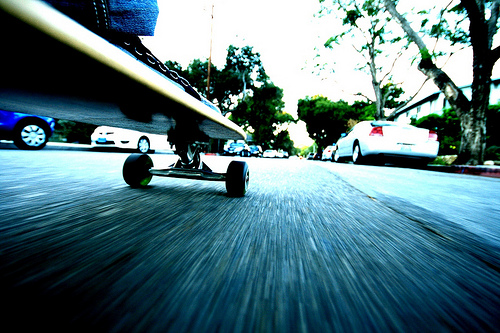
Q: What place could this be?
A: It is a street.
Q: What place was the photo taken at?
A: It was taken at the street.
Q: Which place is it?
A: It is a street.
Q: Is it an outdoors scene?
A: Yes, it is outdoors.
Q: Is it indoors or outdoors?
A: It is outdoors.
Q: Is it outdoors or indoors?
A: It is outdoors.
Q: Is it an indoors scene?
A: No, it is outdoors.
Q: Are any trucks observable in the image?
A: Yes, there is a truck.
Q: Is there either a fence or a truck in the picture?
A: Yes, there is a truck.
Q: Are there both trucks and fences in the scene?
A: No, there is a truck but no fences.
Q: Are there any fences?
A: No, there are no fences.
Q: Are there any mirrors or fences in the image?
A: No, there are no fences or mirrors.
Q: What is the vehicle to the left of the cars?
A: The vehicle is a truck.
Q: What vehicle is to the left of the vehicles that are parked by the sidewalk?
A: The vehicle is a truck.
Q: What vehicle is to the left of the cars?
A: The vehicle is a truck.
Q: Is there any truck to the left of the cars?
A: Yes, there is a truck to the left of the cars.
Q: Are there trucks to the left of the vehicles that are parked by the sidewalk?
A: Yes, there is a truck to the left of the cars.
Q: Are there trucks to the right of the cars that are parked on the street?
A: No, the truck is to the left of the cars.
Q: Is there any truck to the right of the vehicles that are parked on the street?
A: No, the truck is to the left of the cars.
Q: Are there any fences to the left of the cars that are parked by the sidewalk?
A: No, there is a truck to the left of the cars.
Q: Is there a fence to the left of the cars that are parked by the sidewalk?
A: No, there is a truck to the left of the cars.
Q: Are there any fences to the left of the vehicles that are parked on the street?
A: No, there is a truck to the left of the cars.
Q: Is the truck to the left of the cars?
A: Yes, the truck is to the left of the cars.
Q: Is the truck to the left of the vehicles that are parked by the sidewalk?
A: Yes, the truck is to the left of the cars.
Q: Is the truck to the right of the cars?
A: No, the truck is to the left of the cars.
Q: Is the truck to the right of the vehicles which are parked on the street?
A: No, the truck is to the left of the cars.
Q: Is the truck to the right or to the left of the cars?
A: The truck is to the left of the cars.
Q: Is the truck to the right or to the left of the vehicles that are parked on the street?
A: The truck is to the left of the cars.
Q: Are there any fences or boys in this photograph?
A: No, there are no boys or fences.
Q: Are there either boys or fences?
A: No, there are no boys or fences.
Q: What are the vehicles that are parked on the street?
A: The vehicles are cars.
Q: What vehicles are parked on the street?
A: The vehicles are cars.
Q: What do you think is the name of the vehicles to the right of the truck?
A: The vehicles are cars.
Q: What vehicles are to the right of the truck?
A: The vehicles are cars.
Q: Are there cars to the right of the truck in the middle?
A: Yes, there are cars to the right of the truck.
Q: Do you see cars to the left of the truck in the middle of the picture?
A: No, the cars are to the right of the truck.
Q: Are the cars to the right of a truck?
A: Yes, the cars are to the right of a truck.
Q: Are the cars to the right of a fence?
A: No, the cars are to the right of a truck.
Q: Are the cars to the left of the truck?
A: No, the cars are to the right of the truck.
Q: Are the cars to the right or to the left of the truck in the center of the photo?
A: The cars are to the right of the truck.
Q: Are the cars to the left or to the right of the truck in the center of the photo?
A: The cars are to the right of the truck.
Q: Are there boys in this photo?
A: No, there are no boys.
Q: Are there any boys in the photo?
A: No, there are no boys.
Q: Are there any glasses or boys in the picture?
A: No, there are no boys or glasses.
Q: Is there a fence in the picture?
A: No, there are no fences.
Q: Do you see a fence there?
A: No, there are no fences.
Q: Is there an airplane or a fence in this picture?
A: No, there are no fences or airplanes.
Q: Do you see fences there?
A: No, there are no fences.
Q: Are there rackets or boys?
A: No, there are no boys or rackets.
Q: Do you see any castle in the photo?
A: No, there are no castles.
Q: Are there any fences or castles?
A: No, there are no castles or fences.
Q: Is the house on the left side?
A: No, the house is on the right of the image.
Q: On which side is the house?
A: The house is on the right of the image.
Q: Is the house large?
A: Yes, the house is large.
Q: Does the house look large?
A: Yes, the house is large.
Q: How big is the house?
A: The house is large.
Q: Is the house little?
A: No, the house is large.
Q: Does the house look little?
A: No, the house is large.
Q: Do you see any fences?
A: No, there are no fences.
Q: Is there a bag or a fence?
A: No, there are no fences or bags.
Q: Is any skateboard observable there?
A: Yes, there is a skateboard.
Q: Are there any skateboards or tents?
A: Yes, there is a skateboard.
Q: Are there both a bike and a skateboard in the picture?
A: No, there is a skateboard but no bikes.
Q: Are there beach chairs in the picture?
A: No, there are no beach chairs.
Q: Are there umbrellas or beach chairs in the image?
A: No, there are no beach chairs or umbrellas.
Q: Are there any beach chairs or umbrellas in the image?
A: No, there are no beach chairs or umbrellas.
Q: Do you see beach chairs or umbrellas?
A: No, there are no beach chairs or umbrellas.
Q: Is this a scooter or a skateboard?
A: This is a skateboard.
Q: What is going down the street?
A: The skateboard is going down the street.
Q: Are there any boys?
A: No, there are no boys.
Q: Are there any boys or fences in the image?
A: No, there are no boys or fences.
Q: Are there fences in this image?
A: No, there are no fences.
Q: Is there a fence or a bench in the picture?
A: No, there are no fences or benches.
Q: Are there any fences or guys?
A: No, there are no fences or guys.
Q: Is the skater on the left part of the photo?
A: Yes, the skater is on the left of the image.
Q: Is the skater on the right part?
A: No, the skater is on the left of the image.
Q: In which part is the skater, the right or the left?
A: The skater is on the left of the image.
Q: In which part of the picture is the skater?
A: The skater is on the left of the image.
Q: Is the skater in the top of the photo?
A: Yes, the skater is in the top of the image.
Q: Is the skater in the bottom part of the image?
A: No, the skater is in the top of the image.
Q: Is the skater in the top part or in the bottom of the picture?
A: The skater is in the top of the image.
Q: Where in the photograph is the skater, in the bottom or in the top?
A: The skater is in the top of the image.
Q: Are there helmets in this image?
A: No, there are no helmets.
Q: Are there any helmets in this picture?
A: No, there are no helmets.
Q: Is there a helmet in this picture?
A: No, there are no helmets.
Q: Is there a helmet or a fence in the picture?
A: No, there are no helmets or fences.